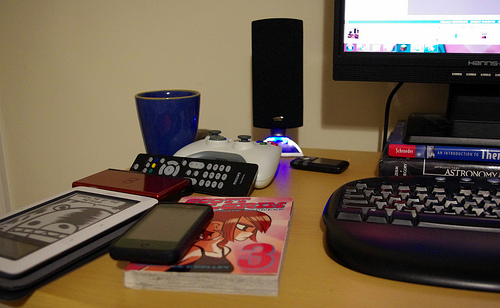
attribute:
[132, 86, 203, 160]
cup — blue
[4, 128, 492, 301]
desk — wooden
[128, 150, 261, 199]
remote control — black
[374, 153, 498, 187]
book — black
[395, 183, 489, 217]
keys — black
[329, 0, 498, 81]
computer monitor — black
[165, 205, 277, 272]
girl — cartoon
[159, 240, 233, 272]
tank top — black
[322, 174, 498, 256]
keyboard — black, ergonomic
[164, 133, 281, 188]
controller — white, xbox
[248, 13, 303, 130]
speaker — black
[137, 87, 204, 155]
mug — blue, ceramic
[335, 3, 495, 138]
monitor — computer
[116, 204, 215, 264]
smart phone — black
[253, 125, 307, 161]
base — glowing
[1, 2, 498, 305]
items — several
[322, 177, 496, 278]
keyboard — black, computer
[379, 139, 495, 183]
stack — small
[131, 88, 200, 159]
mug — blue, ceramic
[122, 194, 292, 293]
book — soft cover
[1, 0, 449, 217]
wall — beige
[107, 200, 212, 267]
cellphone — black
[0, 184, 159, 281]
computer tablet — white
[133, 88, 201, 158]
coffee cup — blue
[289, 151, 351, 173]
cellphone — small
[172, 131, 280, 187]
game controller — white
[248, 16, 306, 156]
computer speaker — black